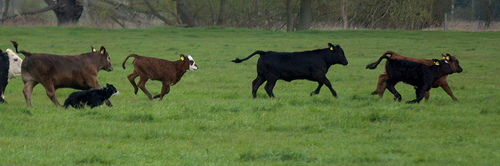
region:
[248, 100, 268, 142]
There is a patch of green grass here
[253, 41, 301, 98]
There is a black cow here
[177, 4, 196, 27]
There are dark brown trunks here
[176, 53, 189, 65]
There is a tag that is yellow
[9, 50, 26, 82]
There is a cow that is white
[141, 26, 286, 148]
This photo has a great deal of detail to it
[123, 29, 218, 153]
This photo was taken in the summer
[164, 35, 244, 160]
This photo looks wonderful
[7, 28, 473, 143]
Animals are running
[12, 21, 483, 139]
Black, brown, and white animals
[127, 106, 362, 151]
Green is color of the glass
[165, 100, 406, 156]
The grass is short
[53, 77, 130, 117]
A baby animal is running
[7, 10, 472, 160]
It is currently daytime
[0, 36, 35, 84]
This animal's head is white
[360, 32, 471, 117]
Black running beside brown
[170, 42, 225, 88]
This animal has white and brown face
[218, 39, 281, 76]
The tail is up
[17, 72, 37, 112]
leg of a cow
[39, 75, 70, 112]
leg of a cow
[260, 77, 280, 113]
leg of a cow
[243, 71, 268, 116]
leg of a cow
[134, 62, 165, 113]
leg of a cow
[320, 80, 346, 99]
leg of a cow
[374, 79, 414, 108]
leg of a cow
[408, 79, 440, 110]
leg of a cow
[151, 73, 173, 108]
leg of a cow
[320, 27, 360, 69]
head of a cow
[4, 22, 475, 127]
A herd of cow running in a grassy field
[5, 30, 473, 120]
A herd of cow running in a grassy field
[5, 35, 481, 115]
A herd of cow running in a grassy field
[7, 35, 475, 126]
A herd of cow running in a grassy field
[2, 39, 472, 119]
A herd of cow running in a grassy field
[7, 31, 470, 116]
A herd of cow running in a grassy field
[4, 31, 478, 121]
A herd of cow running in a grassy field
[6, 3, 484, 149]
cows running through a field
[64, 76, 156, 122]
a dog herding cattle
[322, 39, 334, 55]
a tag on a cows ear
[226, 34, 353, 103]
a big black cow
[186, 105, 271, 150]
lots of lush green glass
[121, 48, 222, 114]
a young cow with a white face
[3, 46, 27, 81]
a large cow with a white face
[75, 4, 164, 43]
a large grey boulder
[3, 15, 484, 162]
a large pasture on a farm